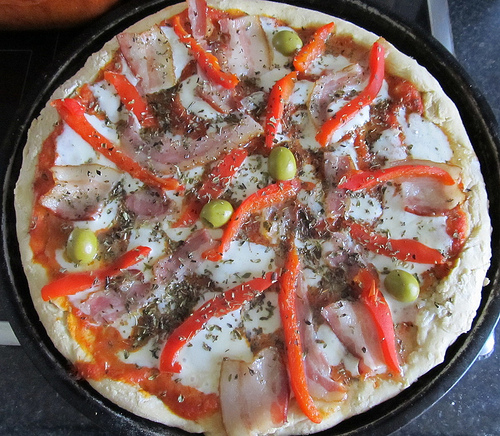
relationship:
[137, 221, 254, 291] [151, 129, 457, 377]
seasonings on pizza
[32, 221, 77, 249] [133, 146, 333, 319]
sauce on pizza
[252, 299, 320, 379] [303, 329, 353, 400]
pepper on bacon